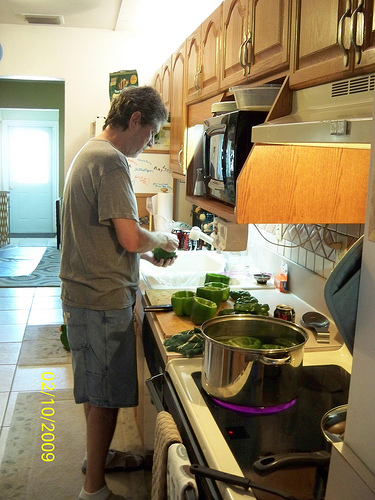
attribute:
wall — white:
[1, 23, 145, 85]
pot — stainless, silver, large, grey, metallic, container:
[190, 310, 313, 414]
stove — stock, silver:
[142, 350, 356, 499]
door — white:
[3, 107, 62, 235]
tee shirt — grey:
[55, 137, 150, 314]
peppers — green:
[164, 266, 258, 316]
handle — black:
[249, 442, 330, 477]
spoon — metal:
[299, 306, 338, 347]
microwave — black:
[197, 110, 263, 208]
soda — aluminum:
[274, 299, 296, 320]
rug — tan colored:
[10, 319, 74, 369]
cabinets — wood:
[154, 0, 374, 87]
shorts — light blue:
[59, 300, 149, 412]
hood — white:
[248, 72, 374, 142]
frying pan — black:
[251, 405, 349, 485]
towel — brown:
[150, 412, 180, 499]